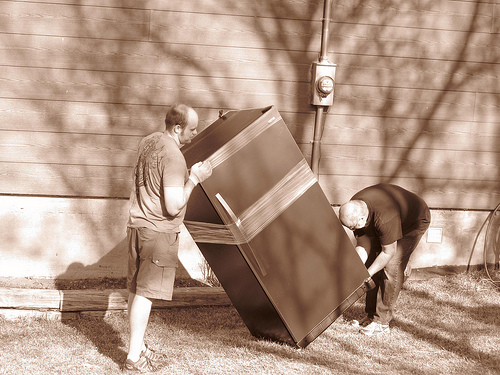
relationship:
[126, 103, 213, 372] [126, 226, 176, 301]
man wearing shorts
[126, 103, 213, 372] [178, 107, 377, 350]
man moving fridge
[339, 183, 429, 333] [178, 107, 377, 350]
man wearing fridge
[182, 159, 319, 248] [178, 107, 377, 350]
tape around fridge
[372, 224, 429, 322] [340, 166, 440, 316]
pants on man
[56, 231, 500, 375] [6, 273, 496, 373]
cast cast on ground